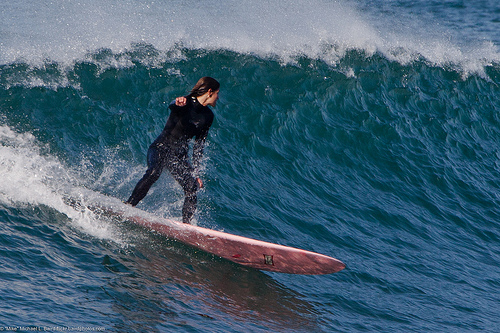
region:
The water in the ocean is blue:
[268, 132, 478, 225]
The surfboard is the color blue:
[67, 179, 349, 284]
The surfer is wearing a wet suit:
[123, 70, 227, 232]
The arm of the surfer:
[159, 87, 192, 116]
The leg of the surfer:
[128, 147, 172, 207]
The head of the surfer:
[189, 70, 226, 111]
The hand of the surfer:
[167, 93, 189, 108]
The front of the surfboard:
[207, 228, 352, 289]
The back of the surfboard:
[63, 176, 165, 248]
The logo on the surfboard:
[226, 247, 288, 275]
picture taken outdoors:
[15, 20, 496, 280]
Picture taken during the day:
[44, 37, 412, 299]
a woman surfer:
[55, 40, 345, 284]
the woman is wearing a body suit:
[142, 81, 214, 229]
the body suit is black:
[144, 68, 224, 250]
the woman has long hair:
[188, 60, 216, 105]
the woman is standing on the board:
[94, 68, 352, 273]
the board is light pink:
[154, 221, 322, 278]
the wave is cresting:
[231, 23, 435, 83]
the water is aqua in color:
[374, 143, 462, 238]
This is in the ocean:
[18, 10, 448, 315]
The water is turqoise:
[262, 76, 470, 250]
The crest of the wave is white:
[29, 38, 451, 72]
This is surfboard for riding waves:
[63, 180, 304, 325]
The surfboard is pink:
[98, 201, 358, 296]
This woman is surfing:
[131, 78, 273, 221]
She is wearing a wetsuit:
[125, 93, 203, 209]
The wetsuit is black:
[108, 80, 233, 202]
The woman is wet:
[72, 23, 286, 257]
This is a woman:
[126, 50, 243, 228]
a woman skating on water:
[44, 51, 395, 330]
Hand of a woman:
[163, 88, 188, 115]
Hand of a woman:
[193, 109, 215, 191]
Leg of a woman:
[169, 151, 204, 224]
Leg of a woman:
[123, 138, 165, 216]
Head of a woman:
[195, 74, 225, 110]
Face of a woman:
[215, 85, 220, 113]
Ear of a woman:
[204, 86, 216, 98]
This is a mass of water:
[246, 37, 496, 273]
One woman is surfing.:
[97, 82, 303, 289]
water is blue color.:
[345, 176, 498, 302]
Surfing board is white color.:
[80, 188, 377, 309]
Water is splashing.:
[6, 140, 103, 201]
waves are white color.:
[31, 18, 478, 73]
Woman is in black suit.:
[139, 75, 206, 202]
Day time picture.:
[4, 45, 395, 293]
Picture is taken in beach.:
[32, 31, 457, 310]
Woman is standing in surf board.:
[90, 119, 217, 270]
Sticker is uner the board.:
[251, 248, 291, 273]